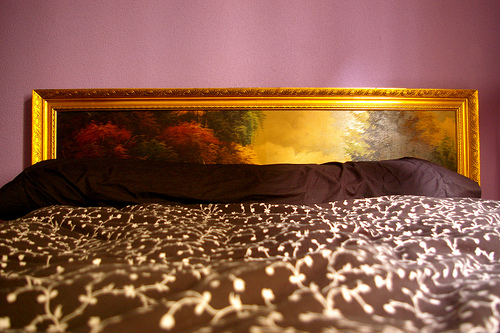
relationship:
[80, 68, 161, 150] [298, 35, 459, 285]
photo in bedroom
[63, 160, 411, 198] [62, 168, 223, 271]
pillow on bed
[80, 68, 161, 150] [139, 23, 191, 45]
photo on wall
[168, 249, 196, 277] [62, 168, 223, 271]
design on bed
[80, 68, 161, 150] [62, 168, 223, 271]
photo behind bed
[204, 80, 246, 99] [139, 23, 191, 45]
frame on wall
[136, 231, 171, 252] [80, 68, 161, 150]
tree in photo